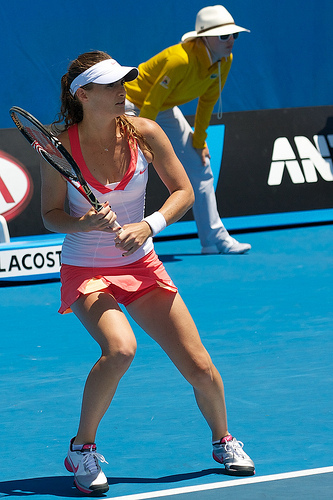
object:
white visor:
[69, 56, 139, 97]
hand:
[114, 221, 153, 258]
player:
[38, 47, 258, 493]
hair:
[46, 50, 156, 162]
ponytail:
[50, 72, 84, 135]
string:
[215, 59, 224, 120]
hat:
[181, 4, 252, 44]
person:
[120, 3, 252, 256]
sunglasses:
[216, 32, 241, 42]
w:
[25, 126, 63, 159]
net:
[13, 111, 77, 180]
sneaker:
[63, 434, 112, 498]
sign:
[68, 454, 80, 473]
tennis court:
[0, 222, 333, 500]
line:
[97, 464, 333, 499]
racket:
[8, 104, 125, 237]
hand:
[80, 200, 121, 233]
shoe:
[210, 434, 257, 478]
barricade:
[0, 0, 330, 286]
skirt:
[57, 248, 178, 315]